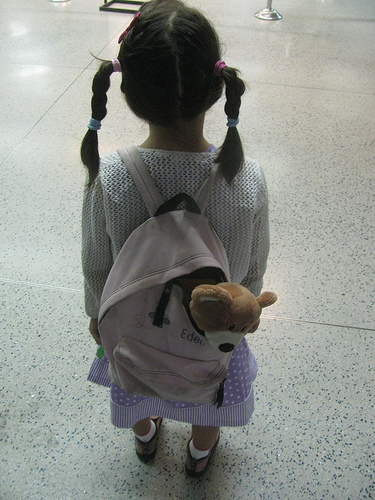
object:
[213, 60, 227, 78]
hair tie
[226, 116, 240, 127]
hair tie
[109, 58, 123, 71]
hair tie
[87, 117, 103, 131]
hair tie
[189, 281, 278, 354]
doll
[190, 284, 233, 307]
ear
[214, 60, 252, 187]
pig tails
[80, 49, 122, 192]
pig tails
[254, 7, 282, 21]
base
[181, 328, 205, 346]
name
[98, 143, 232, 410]
backpack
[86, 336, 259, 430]
cloth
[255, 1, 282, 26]
stand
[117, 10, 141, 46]
clip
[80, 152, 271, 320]
sweater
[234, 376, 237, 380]
dot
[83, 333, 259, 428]
skirt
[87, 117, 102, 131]
band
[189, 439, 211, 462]
sock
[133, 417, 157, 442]
sock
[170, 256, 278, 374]
open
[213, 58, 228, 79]
hair band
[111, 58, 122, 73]
hair band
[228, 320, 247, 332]
eyes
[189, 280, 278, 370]
bear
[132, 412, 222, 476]
feet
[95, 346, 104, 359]
green object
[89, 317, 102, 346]
hand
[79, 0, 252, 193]
hair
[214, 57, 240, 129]
bands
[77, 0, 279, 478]
girl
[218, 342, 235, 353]
black nose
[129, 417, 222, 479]
shoes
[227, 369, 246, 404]
spots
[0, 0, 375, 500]
floor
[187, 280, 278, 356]
head